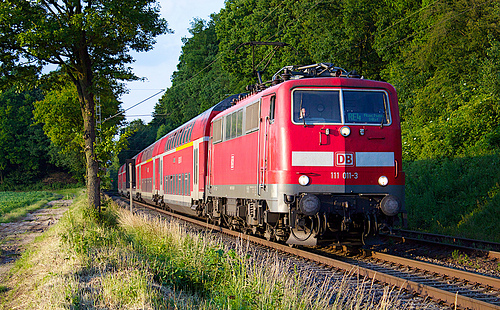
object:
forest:
[0, 0, 500, 245]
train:
[116, 62, 404, 248]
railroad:
[126, 198, 500, 309]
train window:
[175, 128, 182, 146]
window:
[288, 87, 342, 123]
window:
[242, 99, 258, 132]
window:
[344, 92, 395, 126]